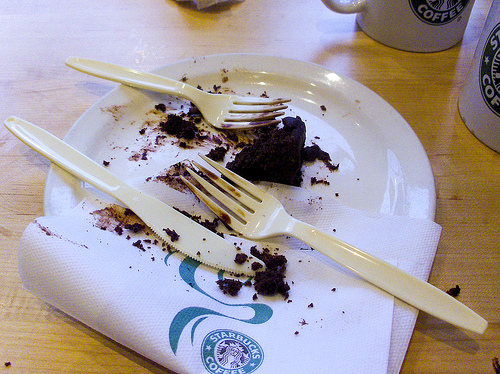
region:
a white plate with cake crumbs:
[17, 56, 427, 308]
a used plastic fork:
[188, 155, 462, 315]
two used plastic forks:
[33, 40, 418, 225]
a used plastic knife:
[36, 150, 298, 306]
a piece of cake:
[218, 99, 313, 193]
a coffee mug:
[328, 2, 480, 65]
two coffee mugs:
[341, 5, 498, 140]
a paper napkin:
[112, 181, 412, 372]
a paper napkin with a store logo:
[133, 255, 356, 367]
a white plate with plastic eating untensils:
[24, 88, 461, 305]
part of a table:
[451, 188, 478, 226]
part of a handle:
[443, 290, 488, 327]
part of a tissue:
[306, 337, 343, 364]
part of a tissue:
[256, 330, 297, 362]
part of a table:
[418, 327, 454, 358]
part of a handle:
[414, 280, 454, 313]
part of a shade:
[101, 327, 144, 354]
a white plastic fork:
[2, 110, 271, 283]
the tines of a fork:
[178, 147, 288, 246]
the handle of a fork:
[283, 210, 493, 339]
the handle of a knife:
[3, 112, 126, 197]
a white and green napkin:
[13, 169, 447, 372]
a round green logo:
[199, 323, 266, 371]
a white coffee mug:
[318, 0, 479, 63]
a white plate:
[42, 48, 439, 230]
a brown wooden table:
[0, 0, 499, 372]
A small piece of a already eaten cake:
[43, 28, 461, 313]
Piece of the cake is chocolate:
[212, 103, 324, 196]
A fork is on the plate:
[176, 148, 498, 345]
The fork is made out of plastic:
[177, 144, 494, 356]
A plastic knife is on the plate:
[1, 107, 272, 293]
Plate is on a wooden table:
[7, 34, 482, 364]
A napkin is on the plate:
[13, 179, 448, 371]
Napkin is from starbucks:
[13, 193, 449, 372]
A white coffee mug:
[319, 0, 486, 62]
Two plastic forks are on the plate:
[58, 48, 492, 345]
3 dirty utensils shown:
[3, 44, 492, 336]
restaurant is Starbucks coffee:
[192, 319, 271, 372]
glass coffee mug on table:
[315, 1, 472, 58]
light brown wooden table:
[446, 153, 493, 263]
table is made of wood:
[20, 313, 77, 369]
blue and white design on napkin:
[156, 251, 282, 373]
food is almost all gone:
[142, 91, 322, 290]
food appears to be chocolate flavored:
[217, 95, 325, 228]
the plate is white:
[32, 51, 446, 229]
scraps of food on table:
[432, 278, 499, 372]